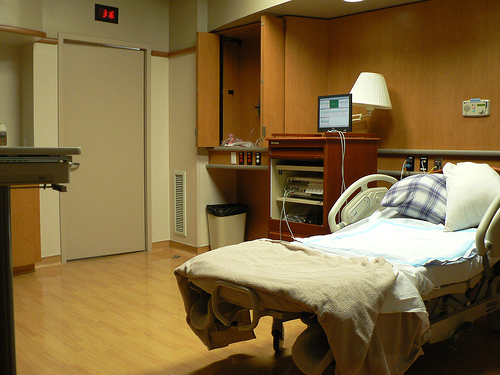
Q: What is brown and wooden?
A: The floor.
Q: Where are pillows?
A: On the bed.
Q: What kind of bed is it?
A: Hospital bed.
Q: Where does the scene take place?
A: In a hospital room.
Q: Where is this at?
A: Hospital room.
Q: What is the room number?
A: 316.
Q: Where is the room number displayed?
A: Over the door.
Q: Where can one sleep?
A: On the bed.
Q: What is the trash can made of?
A: Plastic.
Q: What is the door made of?
A: Metal.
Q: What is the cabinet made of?
A: Wood.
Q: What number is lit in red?
A: 36.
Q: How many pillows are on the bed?
A: 2.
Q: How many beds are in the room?
A: One.